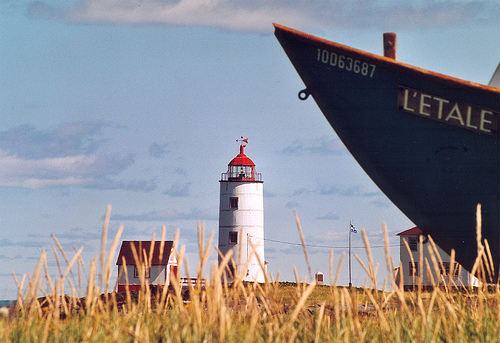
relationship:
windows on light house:
[227, 193, 238, 210] [217, 135, 265, 285]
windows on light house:
[227, 228, 236, 243] [217, 135, 265, 285]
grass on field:
[209, 283, 442, 341] [5, 195, 481, 333]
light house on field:
[216, 134, 268, 286] [2, 277, 499, 342]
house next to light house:
[112, 238, 182, 298] [217, 135, 265, 285]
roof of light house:
[227, 145, 256, 167] [216, 132, 271, 289]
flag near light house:
[346, 221, 358, 288] [216, 132, 271, 289]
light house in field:
[216, 132, 271, 289] [5, 195, 481, 333]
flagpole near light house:
[349, 220, 353, 289] [194, 132, 283, 276]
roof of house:
[113, 235, 189, 272] [115, 236, 180, 300]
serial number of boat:
[311, 42, 379, 81] [274, 21, 498, 282]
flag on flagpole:
[348, 220, 356, 235] [349, 220, 353, 289]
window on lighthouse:
[228, 195, 240, 208] [203, 126, 279, 285]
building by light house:
[108, 238, 178, 300] [216, 134, 268, 286]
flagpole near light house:
[346, 220, 358, 284] [216, 134, 268, 286]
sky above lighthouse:
[0, 0, 499, 297] [218, 135, 267, 282]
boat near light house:
[262, 14, 499, 291] [216, 134, 268, 286]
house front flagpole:
[391, 224, 479, 289] [343, 214, 362, 295]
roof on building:
[115, 240, 174, 266] [108, 233, 186, 291]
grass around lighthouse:
[2, 284, 500, 343] [202, 131, 275, 289]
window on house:
[407, 236, 418, 251] [396, 225, 498, 292]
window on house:
[408, 259, 419, 276] [396, 225, 498, 292]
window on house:
[438, 260, 461, 275] [396, 225, 498, 292]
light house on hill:
[216, 134, 268, 286] [207, 282, 401, 309]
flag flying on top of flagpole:
[350, 222, 363, 233] [348, 220, 353, 283]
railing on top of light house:
[218, 170, 265, 183] [215, 134, 274, 284]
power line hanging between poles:
[246, 233, 400, 248] [245, 217, 356, 285]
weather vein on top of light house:
[231, 131, 251, 149] [166, 103, 320, 323]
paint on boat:
[371, 77, 485, 139] [274, 21, 498, 282]